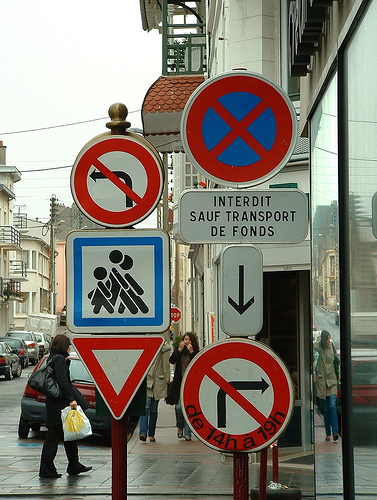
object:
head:
[47, 334, 72, 357]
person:
[39, 335, 93, 481]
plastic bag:
[59, 404, 93, 442]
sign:
[177, 67, 299, 187]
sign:
[64, 228, 171, 332]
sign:
[69, 132, 164, 227]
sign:
[173, 185, 308, 248]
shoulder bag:
[51, 353, 66, 400]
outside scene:
[0, 0, 377, 500]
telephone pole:
[47, 190, 57, 316]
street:
[1, 330, 232, 500]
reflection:
[313, 329, 341, 442]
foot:
[148, 435, 156, 442]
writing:
[185, 404, 287, 450]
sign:
[179, 337, 294, 456]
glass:
[308, 0, 377, 500]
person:
[139, 333, 172, 444]